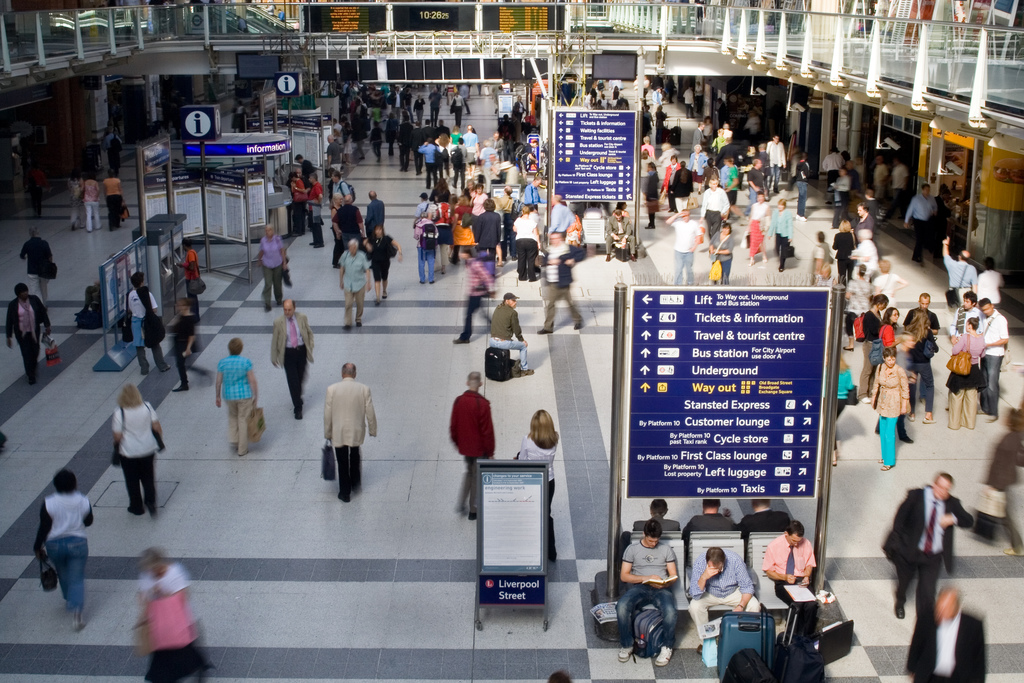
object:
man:
[942, 236, 978, 337]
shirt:
[944, 254, 980, 287]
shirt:
[690, 549, 756, 600]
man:
[688, 546, 762, 654]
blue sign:
[479, 574, 545, 606]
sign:
[555, 111, 637, 201]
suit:
[315, 376, 378, 504]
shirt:
[217, 355, 253, 401]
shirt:
[110, 400, 159, 459]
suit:
[903, 613, 991, 682]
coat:
[449, 390, 496, 458]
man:
[320, 363, 378, 504]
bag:
[321, 439, 337, 481]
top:
[214, 337, 260, 407]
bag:
[484, 347, 514, 383]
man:
[614, 519, 679, 668]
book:
[641, 576, 677, 590]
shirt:
[44, 490, 91, 541]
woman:
[32, 470, 95, 620]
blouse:
[112, 401, 161, 458]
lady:
[216, 337, 266, 456]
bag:
[246, 400, 266, 443]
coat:
[325, 377, 379, 448]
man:
[447, 369, 496, 522]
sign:
[619, 287, 825, 497]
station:
[0, 0, 1024, 681]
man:
[485, 292, 535, 382]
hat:
[503, 292, 520, 299]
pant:
[337, 444, 362, 501]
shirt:
[622, 538, 677, 581]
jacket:
[903, 612, 990, 683]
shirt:
[671, 219, 703, 253]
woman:
[870, 347, 913, 472]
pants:
[879, 414, 899, 465]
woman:
[945, 316, 989, 431]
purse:
[945, 333, 972, 375]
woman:
[110, 382, 165, 515]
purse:
[110, 405, 126, 465]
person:
[517, 409, 560, 563]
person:
[761, 520, 819, 649]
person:
[633, 498, 680, 532]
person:
[682, 499, 736, 541]